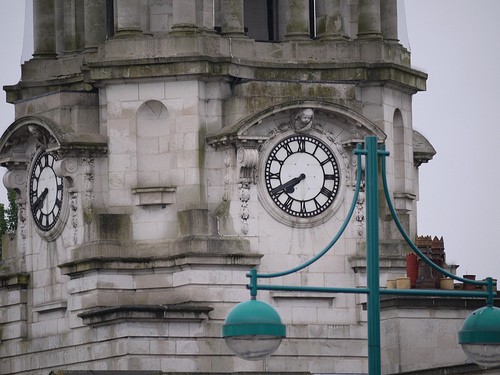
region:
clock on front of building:
[254, 128, 343, 220]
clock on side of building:
[18, 148, 75, 238]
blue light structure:
[215, 130, 497, 366]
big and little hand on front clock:
[267, 170, 312, 206]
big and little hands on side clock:
[30, 183, 50, 216]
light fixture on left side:
[219, 299, 293, 360]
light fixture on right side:
[445, 301, 498, 359]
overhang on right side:
[407, 125, 439, 167]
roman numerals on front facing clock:
[267, 133, 339, 219]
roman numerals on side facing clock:
[17, 148, 75, 228]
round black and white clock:
[259, 127, 349, 225]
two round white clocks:
[4, 120, 355, 267]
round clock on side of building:
[255, 124, 346, 229]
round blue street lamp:
[220, 263, 291, 368]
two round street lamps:
[217, 275, 493, 373]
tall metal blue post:
[348, 132, 408, 364]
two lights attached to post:
[224, 135, 493, 367]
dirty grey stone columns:
[26, 1, 423, 101]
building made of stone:
[12, 55, 409, 373]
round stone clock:
[247, 113, 354, 239]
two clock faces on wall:
[13, 129, 355, 243]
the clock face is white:
[232, 118, 354, 248]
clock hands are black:
[243, 143, 341, 240]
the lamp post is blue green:
[167, 89, 499, 373]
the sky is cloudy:
[429, 33, 484, 281]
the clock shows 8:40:
[267, 147, 338, 240]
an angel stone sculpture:
[286, 106, 351, 154]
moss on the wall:
[232, 72, 394, 122]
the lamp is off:
[208, 265, 302, 358]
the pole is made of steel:
[351, 116, 417, 360]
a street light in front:
[226, 296, 335, 369]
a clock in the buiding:
[261, 128, 342, 224]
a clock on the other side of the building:
[10, 143, 79, 245]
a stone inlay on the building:
[398, 57, 430, 99]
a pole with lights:
[353, 123, 385, 374]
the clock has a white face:
[266, 138, 339, 232]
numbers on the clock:
[268, 133, 346, 232]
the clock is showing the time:
[261, 118, 338, 236]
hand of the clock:
[275, 171, 311, 201]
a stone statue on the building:
[291, 104, 318, 138]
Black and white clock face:
[17, 148, 67, 235]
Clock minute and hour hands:
[32, 186, 48, 207]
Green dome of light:
[219, 301, 288, 336]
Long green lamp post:
[362, 131, 383, 373]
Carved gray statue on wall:
[295, 106, 315, 134]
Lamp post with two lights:
[220, 121, 498, 372]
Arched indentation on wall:
[127, 98, 177, 190]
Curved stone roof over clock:
[217, 106, 390, 145]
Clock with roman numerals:
[267, 133, 341, 225]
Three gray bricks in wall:
[106, 78, 206, 105]